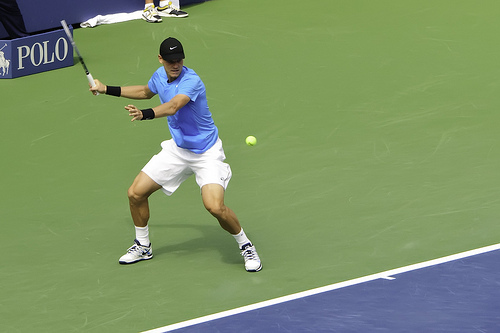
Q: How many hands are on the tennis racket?
A: One.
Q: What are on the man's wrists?
A: Wristbands.